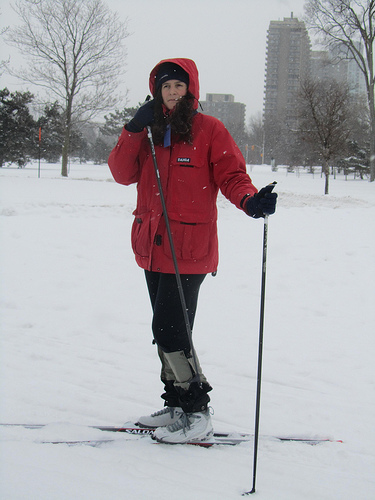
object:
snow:
[1, 158, 375, 498]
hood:
[145, 57, 201, 118]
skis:
[3, 416, 348, 450]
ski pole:
[242, 200, 271, 496]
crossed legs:
[152, 271, 211, 413]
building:
[259, 10, 314, 161]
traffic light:
[261, 134, 267, 168]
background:
[1, 0, 375, 499]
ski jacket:
[108, 50, 259, 272]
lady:
[107, 56, 280, 446]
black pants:
[144, 268, 208, 410]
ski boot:
[151, 410, 221, 448]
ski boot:
[132, 402, 186, 436]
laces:
[169, 414, 192, 435]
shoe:
[154, 412, 216, 450]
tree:
[3, 0, 130, 177]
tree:
[0, 84, 37, 168]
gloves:
[125, 94, 160, 131]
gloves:
[246, 177, 280, 217]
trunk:
[60, 93, 74, 176]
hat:
[155, 62, 190, 89]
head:
[157, 62, 190, 111]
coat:
[107, 55, 259, 276]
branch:
[27, 78, 67, 102]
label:
[175, 156, 189, 165]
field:
[0, 162, 375, 499]